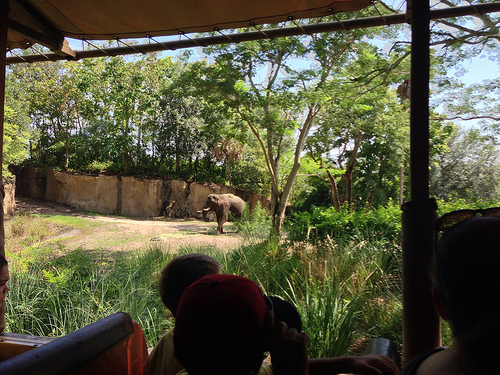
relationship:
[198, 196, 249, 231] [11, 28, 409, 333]
elephant in exhibit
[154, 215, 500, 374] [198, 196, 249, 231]
children watch elephant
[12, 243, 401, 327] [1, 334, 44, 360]
grass behind fence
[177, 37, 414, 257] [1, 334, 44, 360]
tree behind fence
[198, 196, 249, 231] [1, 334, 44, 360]
elephant behind fence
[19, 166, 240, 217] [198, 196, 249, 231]
stones behind elephant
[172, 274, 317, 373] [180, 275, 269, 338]
boy wears cap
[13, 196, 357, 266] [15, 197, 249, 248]
ground has dirt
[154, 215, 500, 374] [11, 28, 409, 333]
people watching exhibit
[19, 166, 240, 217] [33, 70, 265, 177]
stones hold trees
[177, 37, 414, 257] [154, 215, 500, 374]
tree in front of children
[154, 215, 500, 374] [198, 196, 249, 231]
children look at elephant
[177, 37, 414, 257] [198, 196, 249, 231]
tree near elephant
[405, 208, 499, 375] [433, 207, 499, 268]
person wears sunglasses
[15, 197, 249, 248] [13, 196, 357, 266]
dirt on ground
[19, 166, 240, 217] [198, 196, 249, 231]
wall behind elephant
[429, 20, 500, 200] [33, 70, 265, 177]
sky behind trees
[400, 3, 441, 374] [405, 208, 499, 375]
pole near person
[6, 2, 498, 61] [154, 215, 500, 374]
canopy over children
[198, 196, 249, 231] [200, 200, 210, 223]
elephant has trunk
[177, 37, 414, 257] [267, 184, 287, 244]
tree has trunk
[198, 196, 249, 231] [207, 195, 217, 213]
elephant has head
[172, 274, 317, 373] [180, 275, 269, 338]
boy has cap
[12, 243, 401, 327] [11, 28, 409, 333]
grass in exhibit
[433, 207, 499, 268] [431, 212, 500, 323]
sunglasses on head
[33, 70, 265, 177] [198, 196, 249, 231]
trees above elephant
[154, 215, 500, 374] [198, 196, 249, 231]
children observing elephant